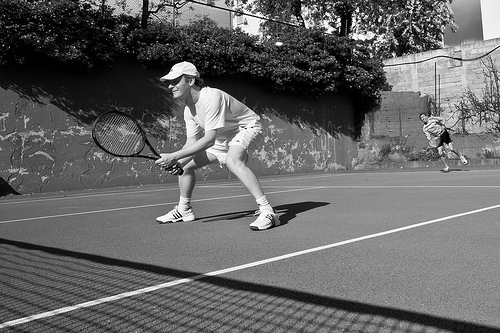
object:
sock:
[254, 196, 274, 215]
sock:
[176, 195, 191, 212]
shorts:
[205, 118, 262, 165]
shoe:
[248, 208, 281, 230]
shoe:
[155, 203, 196, 224]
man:
[156, 60, 282, 230]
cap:
[160, 60, 202, 81]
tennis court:
[0, 169, 500, 331]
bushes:
[4, 2, 379, 110]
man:
[417, 111, 468, 173]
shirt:
[182, 85, 262, 139]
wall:
[379, 41, 499, 133]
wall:
[3, 74, 419, 198]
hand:
[154, 152, 177, 170]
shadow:
[195, 188, 331, 227]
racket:
[91, 110, 185, 176]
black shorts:
[434, 131, 454, 145]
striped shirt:
[421, 115, 446, 143]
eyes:
[173, 80, 179, 83]